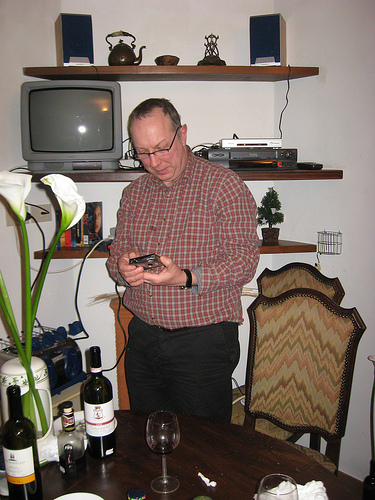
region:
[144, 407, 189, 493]
A tall wine glass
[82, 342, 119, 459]
A bottle of wine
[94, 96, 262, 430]
A man in a red checkered shirt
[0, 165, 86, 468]
A large white lily plant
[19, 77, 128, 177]
A small TV on the shelf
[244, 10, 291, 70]
A wood speaker on the shelf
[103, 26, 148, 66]
A small metal kettle on the shelf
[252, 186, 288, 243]
A small decorative tree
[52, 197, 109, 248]
A collection of DVDs on the shelf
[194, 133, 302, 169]
Electronic consoles on the shelf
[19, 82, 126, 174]
a gray TV on shelf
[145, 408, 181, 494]
an almost empty glass of red wine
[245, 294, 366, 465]
wooden frame of a stuffed chair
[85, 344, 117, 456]
an opened bottle of red wine on a table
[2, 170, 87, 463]
calla flowers in a pot on a table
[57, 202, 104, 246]
a stack of books on a shelf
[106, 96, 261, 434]
a man standing next to a table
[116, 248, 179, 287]
man holding a silver camera in his hands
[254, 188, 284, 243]
a small Christmas tree on a shelf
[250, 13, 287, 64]
a black and silver speaker on a shelf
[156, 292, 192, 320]
the shirt is plaid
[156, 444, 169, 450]
the liquid is dark red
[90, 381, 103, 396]
the wine bottle is on the table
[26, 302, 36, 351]
the stem is green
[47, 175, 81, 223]
the flower is white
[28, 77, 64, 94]
the tv is gray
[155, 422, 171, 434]
the glass is clear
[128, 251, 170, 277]
the man is looking at the camera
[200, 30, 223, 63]
the statue is bronze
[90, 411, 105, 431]
the lable is red and white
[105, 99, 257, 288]
man looking slightly perplexed by object in her hands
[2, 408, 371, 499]
a dark table with a rounded edge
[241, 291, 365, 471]
dining chair next to table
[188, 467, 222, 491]
crumpled small piece of paper on table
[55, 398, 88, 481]
mostly empty small bottle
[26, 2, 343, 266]
shelves set in oddly shaped corner of room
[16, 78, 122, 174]
a small grey television set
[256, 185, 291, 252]
small holiday themed decorative item on shelf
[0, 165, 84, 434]
tall calla lillies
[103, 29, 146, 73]
small teapot with antique appearance on shelf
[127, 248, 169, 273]
A camera in the mans hands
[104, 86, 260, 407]
The man looks down at the camera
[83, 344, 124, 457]
A wine bottle on the table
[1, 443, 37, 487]
A white and orange label on th bottle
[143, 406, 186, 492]
A wine glass with red wine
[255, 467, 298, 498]
The top of a clear wine glass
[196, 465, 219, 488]
a piece of paper wrapper on the table top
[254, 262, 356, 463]
Chairs with a stratic cushion design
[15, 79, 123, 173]
A small grey tv on the shelf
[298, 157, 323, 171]
a black tv remote on the shelf